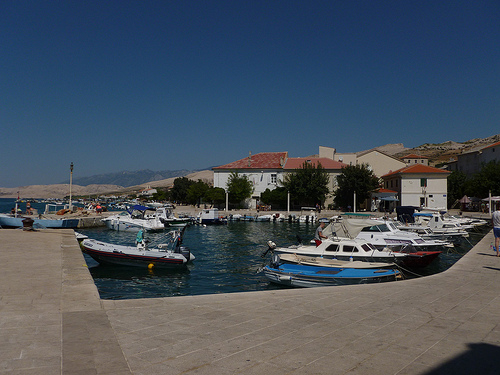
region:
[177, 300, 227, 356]
part of a ground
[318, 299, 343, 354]
part of a floor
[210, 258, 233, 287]
part of a water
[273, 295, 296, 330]
part of a floor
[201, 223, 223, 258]
part of a water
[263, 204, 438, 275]
series of boats in water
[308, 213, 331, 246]
man on boat in water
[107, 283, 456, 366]
tile deck surrounding water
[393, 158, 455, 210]
one of several buildings in background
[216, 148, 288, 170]
red roof on building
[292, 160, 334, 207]
tree near building behind boats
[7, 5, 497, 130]
clear blue sky outside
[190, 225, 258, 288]
deep blue water where boats are parked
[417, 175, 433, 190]
window on building behind boats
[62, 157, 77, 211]
post behind boats in background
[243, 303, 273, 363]
part of a floor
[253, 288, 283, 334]
part of a floor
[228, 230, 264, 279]
part of a water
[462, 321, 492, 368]
part of a shade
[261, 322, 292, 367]
part of a floor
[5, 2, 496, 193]
blue of daytime sky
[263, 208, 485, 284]
row of docked boats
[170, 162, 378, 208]
green leaves on trees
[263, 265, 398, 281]
blue top of boat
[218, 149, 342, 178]
red roof of building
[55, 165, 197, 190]
hazy mountain on horizon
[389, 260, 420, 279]
rope on tip of boat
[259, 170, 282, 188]
window on white wall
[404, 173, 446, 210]
two windows on buildings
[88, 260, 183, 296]
reflection on water surface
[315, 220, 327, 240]
The gray shirt the guy on the boat is wearing.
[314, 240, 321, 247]
The red shorts the guy on the boat is wearing.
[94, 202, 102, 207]
The person in the distance wearing a pink shirt.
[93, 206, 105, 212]
The person in the distance wearing gray shorts.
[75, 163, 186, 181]
The mountains in the distance.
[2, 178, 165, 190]
The sand dunes in the distance.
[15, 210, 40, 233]
The black trash can on the platform.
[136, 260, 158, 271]
The yellow ball on the side of the boat.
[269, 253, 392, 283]
The blue boat next to the man on the boat.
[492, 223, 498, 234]
The blue shorts the man on the right is wearing.